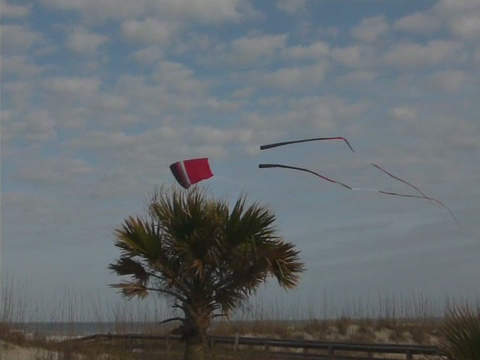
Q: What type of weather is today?
A: It is cloudy.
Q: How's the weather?
A: It is cloudy.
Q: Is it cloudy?
A: Yes, it is cloudy.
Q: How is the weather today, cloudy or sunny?
A: It is cloudy.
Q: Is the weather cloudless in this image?
A: No, it is cloudy.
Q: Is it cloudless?
A: No, it is cloudy.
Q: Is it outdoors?
A: Yes, it is outdoors.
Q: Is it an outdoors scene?
A: Yes, it is outdoors.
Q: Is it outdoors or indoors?
A: It is outdoors.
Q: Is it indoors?
A: No, it is outdoors.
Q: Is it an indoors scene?
A: No, it is outdoors.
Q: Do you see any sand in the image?
A: Yes, there is sand.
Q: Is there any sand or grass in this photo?
A: Yes, there is sand.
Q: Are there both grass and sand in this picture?
A: Yes, there are both sand and grass.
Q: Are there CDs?
A: No, there are no cds.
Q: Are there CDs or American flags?
A: No, there are no CDs or American flags.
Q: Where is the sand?
A: The sand is on the beach.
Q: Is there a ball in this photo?
A: No, there are no balls.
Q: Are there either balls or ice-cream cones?
A: No, there are no balls or ice-cream cones.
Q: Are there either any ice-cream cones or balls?
A: No, there are no balls or ice-cream cones.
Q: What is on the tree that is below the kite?
A: The leaves are on the palm tree.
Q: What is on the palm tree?
A: The leaves are on the palm tree.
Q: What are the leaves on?
A: The leaves are on the palm.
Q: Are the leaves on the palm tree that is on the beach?
A: Yes, the leaves are on the palm.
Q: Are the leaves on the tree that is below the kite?
A: Yes, the leaves are on the palm.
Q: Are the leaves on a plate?
A: No, the leaves are on the palm.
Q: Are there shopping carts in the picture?
A: No, there are no shopping carts.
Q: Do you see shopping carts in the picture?
A: No, there are no shopping carts.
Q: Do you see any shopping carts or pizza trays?
A: No, there are no shopping carts or pizza trays.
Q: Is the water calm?
A: Yes, the water is calm.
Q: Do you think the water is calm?
A: Yes, the water is calm.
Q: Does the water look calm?
A: Yes, the water is calm.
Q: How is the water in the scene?
A: The water is calm.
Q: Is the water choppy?
A: No, the water is calm.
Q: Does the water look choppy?
A: No, the water is calm.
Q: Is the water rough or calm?
A: The water is calm.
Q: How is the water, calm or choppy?
A: The water is calm.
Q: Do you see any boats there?
A: No, there are no boats.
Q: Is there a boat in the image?
A: No, there are no boats.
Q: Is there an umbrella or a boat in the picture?
A: No, there are no boats or umbrellas.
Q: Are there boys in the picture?
A: No, there are no boys.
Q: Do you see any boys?
A: No, there are no boys.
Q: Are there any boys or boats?
A: No, there are no boys or boats.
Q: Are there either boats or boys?
A: No, there are no boys or boats.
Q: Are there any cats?
A: No, there are no cats.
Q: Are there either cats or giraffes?
A: No, there are no cats or giraffes.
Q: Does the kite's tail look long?
A: Yes, the tail is long.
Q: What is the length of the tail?
A: The tail is long.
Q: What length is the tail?
A: The tail is long.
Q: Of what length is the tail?
A: The tail is long.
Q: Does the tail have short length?
A: No, the tail is long.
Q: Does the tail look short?
A: No, the tail is long.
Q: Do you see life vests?
A: No, there are no life vests.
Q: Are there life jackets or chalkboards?
A: No, there are no life jackets or chalkboards.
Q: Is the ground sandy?
A: Yes, the ground is sandy.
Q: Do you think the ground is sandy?
A: Yes, the ground is sandy.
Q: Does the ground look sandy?
A: Yes, the ground is sandy.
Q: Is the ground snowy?
A: No, the ground is sandy.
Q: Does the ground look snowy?
A: No, the ground is sandy.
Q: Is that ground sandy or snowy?
A: The ground is sandy.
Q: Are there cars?
A: No, there are no cars.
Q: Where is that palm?
A: The palm is on the beach.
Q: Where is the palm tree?
A: The palm is on the beach.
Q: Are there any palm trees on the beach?
A: Yes, there is a palm tree on the beach.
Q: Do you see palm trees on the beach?
A: Yes, there is a palm tree on the beach.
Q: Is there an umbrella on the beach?
A: No, there is a palm tree on the beach.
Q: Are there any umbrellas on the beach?
A: No, there is a palm tree on the beach.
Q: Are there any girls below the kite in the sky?
A: No, there is a palm tree below the kite.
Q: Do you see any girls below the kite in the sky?
A: No, there is a palm tree below the kite.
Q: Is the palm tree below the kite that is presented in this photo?
A: Yes, the palm tree is below the kite.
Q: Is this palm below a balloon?
A: No, the palm is below the kite.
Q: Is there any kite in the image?
A: Yes, there is a kite.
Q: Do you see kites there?
A: Yes, there is a kite.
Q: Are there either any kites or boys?
A: Yes, there is a kite.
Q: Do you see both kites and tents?
A: No, there is a kite but no tents.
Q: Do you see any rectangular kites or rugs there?
A: Yes, there is a rectangular kite.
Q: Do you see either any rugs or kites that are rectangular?
A: Yes, the kite is rectangular.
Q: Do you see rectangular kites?
A: Yes, there is a rectangular kite.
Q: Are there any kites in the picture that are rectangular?
A: Yes, there is a kite that is rectangular.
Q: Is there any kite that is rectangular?
A: Yes, there is a kite that is rectangular.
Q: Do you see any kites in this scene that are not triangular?
A: Yes, there is a rectangular kite.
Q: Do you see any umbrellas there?
A: No, there are no umbrellas.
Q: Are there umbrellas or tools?
A: No, there are no umbrellas or tools.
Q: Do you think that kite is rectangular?
A: Yes, the kite is rectangular.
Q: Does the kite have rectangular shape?
A: Yes, the kite is rectangular.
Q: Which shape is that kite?
A: The kite is rectangular.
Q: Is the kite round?
A: No, the kite is rectangular.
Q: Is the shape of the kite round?
A: No, the kite is rectangular.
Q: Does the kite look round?
A: No, the kite is rectangular.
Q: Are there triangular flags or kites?
A: No, there is a kite but it is rectangular.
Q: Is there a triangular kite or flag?
A: No, there is a kite but it is rectangular.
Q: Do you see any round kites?
A: No, there is a kite but it is rectangular.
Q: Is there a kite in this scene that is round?
A: No, there is a kite but it is rectangular.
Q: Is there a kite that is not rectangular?
A: No, there is a kite but it is rectangular.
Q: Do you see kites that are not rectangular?
A: No, there is a kite but it is rectangular.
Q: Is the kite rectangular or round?
A: The kite is rectangular.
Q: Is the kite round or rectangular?
A: The kite is rectangular.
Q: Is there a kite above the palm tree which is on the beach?
A: Yes, there is a kite above the palm.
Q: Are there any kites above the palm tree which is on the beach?
A: Yes, there is a kite above the palm.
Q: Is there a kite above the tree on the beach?
A: Yes, there is a kite above the palm.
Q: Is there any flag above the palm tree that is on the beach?
A: No, there is a kite above the palm.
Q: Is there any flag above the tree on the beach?
A: No, there is a kite above the palm.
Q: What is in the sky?
A: The kite is in the sky.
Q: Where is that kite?
A: The kite is in the sky.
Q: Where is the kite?
A: The kite is in the sky.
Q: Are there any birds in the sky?
A: No, there is a kite in the sky.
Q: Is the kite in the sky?
A: Yes, the kite is in the sky.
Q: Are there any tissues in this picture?
A: No, there are no tissues.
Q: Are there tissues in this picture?
A: No, there are no tissues.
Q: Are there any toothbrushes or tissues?
A: No, there are no tissues or toothbrushes.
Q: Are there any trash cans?
A: No, there are no trash cans.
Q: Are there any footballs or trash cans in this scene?
A: No, there are no trash cans or footballs.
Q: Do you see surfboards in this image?
A: No, there are no surfboards.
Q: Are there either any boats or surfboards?
A: No, there are no surfboards or boats.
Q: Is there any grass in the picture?
A: Yes, there is grass.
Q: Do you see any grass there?
A: Yes, there is grass.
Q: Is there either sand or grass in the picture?
A: Yes, there is grass.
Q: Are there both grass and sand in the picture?
A: Yes, there are both grass and sand.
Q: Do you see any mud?
A: No, there is no mud.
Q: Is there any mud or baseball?
A: No, there are no mud or baseballs.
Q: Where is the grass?
A: The grass is on the beach.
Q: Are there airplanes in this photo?
A: No, there are no airplanes.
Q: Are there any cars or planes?
A: No, there are no planes or cars.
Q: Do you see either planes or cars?
A: No, there are no planes or cars.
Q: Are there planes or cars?
A: No, there are no planes or cars.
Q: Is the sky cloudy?
A: Yes, the sky is cloudy.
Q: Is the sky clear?
A: No, the sky is cloudy.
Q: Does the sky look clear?
A: No, the sky is cloudy.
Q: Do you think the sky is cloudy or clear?
A: The sky is cloudy.